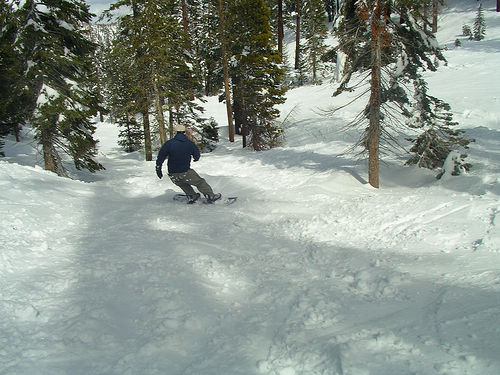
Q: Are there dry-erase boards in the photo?
A: No, there are no dry-erase boards.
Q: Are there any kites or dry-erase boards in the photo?
A: No, there are no dry-erase boards or kites.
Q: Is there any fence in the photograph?
A: No, there are no fences.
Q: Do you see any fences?
A: No, there are no fences.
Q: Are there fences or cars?
A: No, there are no fences or cars.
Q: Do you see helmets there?
A: No, there are no helmets.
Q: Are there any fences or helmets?
A: No, there are no helmets or fences.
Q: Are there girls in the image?
A: No, there are no girls.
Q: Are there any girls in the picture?
A: No, there are no girls.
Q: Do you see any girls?
A: No, there are no girls.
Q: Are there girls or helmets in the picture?
A: No, there are no girls or helmets.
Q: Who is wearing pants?
A: The man is wearing pants.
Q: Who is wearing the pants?
A: The man is wearing pants.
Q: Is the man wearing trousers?
A: Yes, the man is wearing trousers.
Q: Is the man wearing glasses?
A: No, the man is wearing trousers.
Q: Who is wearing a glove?
A: The man is wearing a glove.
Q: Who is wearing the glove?
A: The man is wearing a glove.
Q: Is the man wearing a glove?
A: Yes, the man is wearing a glove.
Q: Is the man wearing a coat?
A: No, the man is wearing a glove.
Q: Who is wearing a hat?
A: The man is wearing a hat.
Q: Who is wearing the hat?
A: The man is wearing a hat.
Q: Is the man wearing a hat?
A: Yes, the man is wearing a hat.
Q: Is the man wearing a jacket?
A: No, the man is wearing a hat.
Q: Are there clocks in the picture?
A: Yes, there is a clock.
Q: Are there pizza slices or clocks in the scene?
A: Yes, there is a clock.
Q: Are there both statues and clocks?
A: No, there is a clock but no statues.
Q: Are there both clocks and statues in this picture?
A: No, there is a clock but no statues.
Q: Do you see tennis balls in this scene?
A: No, there are no tennis balls.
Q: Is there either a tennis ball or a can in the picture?
A: No, there are no tennis balls or cans.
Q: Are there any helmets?
A: No, there are no helmets.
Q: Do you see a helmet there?
A: No, there are no helmets.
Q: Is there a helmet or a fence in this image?
A: No, there are no helmets or fences.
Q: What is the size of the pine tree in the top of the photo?
A: The pine tree is small.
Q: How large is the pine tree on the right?
A: The pine tree is small.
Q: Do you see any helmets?
A: No, there are no helmets.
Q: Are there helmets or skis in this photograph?
A: No, there are no helmets or skis.